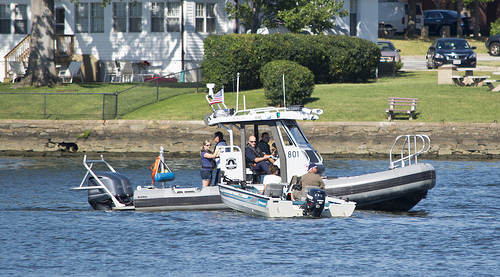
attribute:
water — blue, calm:
[4, 151, 499, 276]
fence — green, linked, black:
[0, 66, 208, 122]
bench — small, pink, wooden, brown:
[390, 98, 417, 123]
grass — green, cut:
[140, 60, 495, 120]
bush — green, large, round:
[263, 62, 315, 106]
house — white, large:
[0, 0, 377, 83]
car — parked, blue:
[430, 41, 477, 64]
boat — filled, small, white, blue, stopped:
[212, 101, 354, 219]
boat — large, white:
[87, 108, 436, 212]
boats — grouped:
[90, 108, 447, 223]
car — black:
[416, 10, 474, 35]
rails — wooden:
[0, 34, 76, 76]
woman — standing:
[201, 139, 213, 187]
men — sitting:
[247, 129, 282, 173]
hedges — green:
[206, 35, 381, 86]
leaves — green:
[232, 1, 333, 28]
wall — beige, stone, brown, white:
[0, 117, 499, 157]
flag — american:
[205, 87, 229, 109]